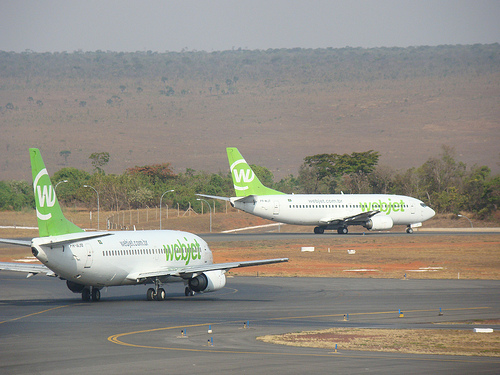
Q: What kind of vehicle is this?
A: A large plane.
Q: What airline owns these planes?
A: Webjet.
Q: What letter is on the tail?
A: W.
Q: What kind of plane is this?
A: A white and green plane.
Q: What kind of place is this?
A: A runway.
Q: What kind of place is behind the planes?
A: A desert like empty field.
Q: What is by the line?
A: Small blue lights.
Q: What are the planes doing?
A: Driving along the runway.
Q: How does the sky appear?
A: Hazy.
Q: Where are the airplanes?
A: On the runway.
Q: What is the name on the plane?
A: Webjet.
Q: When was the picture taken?
A: Daytime.